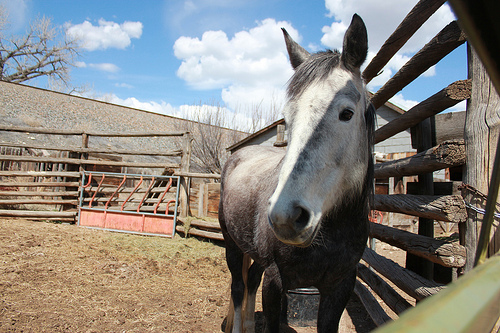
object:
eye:
[337, 104, 355, 123]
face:
[269, 52, 368, 245]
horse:
[214, 12, 377, 332]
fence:
[324, 4, 500, 331]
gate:
[81, 169, 182, 237]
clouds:
[67, 19, 141, 55]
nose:
[264, 175, 327, 240]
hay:
[74, 252, 146, 291]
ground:
[0, 211, 228, 332]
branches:
[36, 71, 68, 83]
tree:
[3, 20, 71, 88]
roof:
[1, 77, 261, 173]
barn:
[1, 78, 250, 241]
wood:
[470, 117, 498, 176]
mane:
[292, 53, 327, 87]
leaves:
[55, 66, 68, 81]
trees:
[177, 106, 227, 186]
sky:
[170, 0, 330, 96]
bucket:
[285, 286, 320, 326]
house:
[219, 83, 426, 250]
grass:
[1, 213, 347, 332]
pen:
[3, 0, 498, 333]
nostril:
[291, 203, 314, 225]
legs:
[227, 250, 356, 331]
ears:
[337, 11, 369, 71]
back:
[232, 144, 287, 166]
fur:
[239, 156, 258, 199]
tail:
[219, 188, 236, 290]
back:
[373, 74, 467, 206]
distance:
[4, 27, 479, 120]